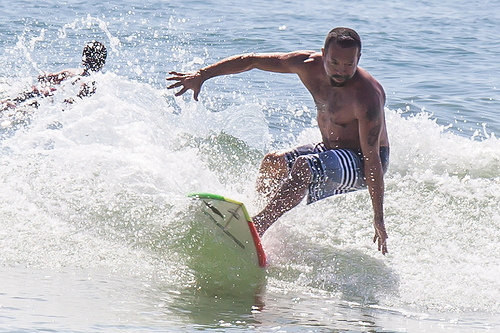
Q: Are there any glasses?
A: No, there are no glasses.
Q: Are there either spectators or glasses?
A: No, there are no glasses or spectators.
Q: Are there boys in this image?
A: No, there are no boys.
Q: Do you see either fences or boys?
A: No, there are no boys or fences.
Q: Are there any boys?
A: No, there are no boys.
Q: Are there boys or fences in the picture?
A: No, there are no boys or fences.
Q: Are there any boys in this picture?
A: No, there are no boys.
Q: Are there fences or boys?
A: No, there are no boys or fences.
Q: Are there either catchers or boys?
A: No, there are no boys or catchers.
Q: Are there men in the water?
A: Yes, there is a man in the water.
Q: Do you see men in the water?
A: Yes, there is a man in the water.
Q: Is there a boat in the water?
A: No, there is a man in the water.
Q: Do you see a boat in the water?
A: No, there is a man in the water.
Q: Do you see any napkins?
A: No, there are no napkins.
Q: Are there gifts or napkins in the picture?
A: No, there are no napkins or gifts.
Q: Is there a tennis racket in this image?
A: No, there are no rackets.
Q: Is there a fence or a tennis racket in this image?
A: No, there are no rackets or fences.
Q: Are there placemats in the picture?
A: No, there are no placemats.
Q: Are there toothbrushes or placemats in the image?
A: No, there are no placemats or toothbrushes.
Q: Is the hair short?
A: Yes, the hair is short.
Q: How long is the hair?
A: The hair is short.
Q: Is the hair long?
A: No, the hair is short.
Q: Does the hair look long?
A: No, the hair is short.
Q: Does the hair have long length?
A: No, the hair is short.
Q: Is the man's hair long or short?
A: The hair is short.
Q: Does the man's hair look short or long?
A: The hair is short.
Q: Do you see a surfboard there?
A: Yes, there is a surfboard.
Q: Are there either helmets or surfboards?
A: Yes, there is a surfboard.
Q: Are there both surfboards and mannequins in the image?
A: No, there is a surfboard but no mannequins.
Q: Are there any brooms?
A: No, there are no brooms.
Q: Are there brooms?
A: No, there are no brooms.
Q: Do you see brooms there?
A: No, there are no brooms.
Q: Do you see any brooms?
A: No, there are no brooms.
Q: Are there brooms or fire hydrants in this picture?
A: No, there are no brooms or fire hydrants.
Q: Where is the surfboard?
A: The surfboard is in the water.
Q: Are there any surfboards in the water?
A: Yes, there is a surfboard in the water.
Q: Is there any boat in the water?
A: No, there is a surfboard in the water.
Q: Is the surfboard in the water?
A: Yes, the surfboard is in the water.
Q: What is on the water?
A: The surfboard is on the water.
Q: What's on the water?
A: The surfboard is on the water.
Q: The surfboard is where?
A: The surfboard is on the water.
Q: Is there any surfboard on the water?
A: Yes, there is a surfboard on the water.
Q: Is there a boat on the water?
A: No, there is a surfboard on the water.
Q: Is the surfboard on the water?
A: Yes, the surfboard is on the water.